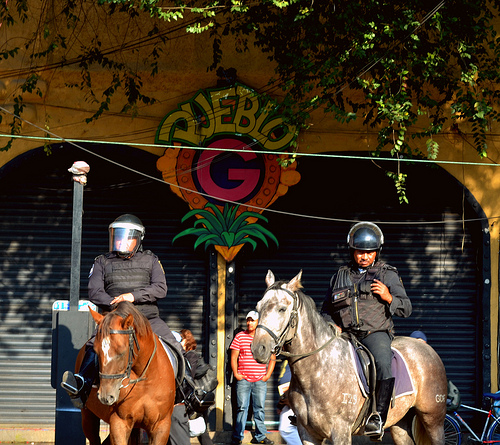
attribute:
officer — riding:
[327, 217, 418, 444]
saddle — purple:
[344, 333, 419, 402]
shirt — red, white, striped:
[229, 327, 274, 385]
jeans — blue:
[234, 376, 269, 442]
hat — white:
[245, 309, 260, 321]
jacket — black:
[319, 259, 416, 339]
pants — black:
[342, 324, 399, 414]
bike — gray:
[417, 382, 499, 445]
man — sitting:
[53, 207, 213, 420]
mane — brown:
[96, 298, 148, 345]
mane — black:
[268, 276, 333, 343]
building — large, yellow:
[3, 0, 500, 427]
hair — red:
[176, 327, 204, 354]